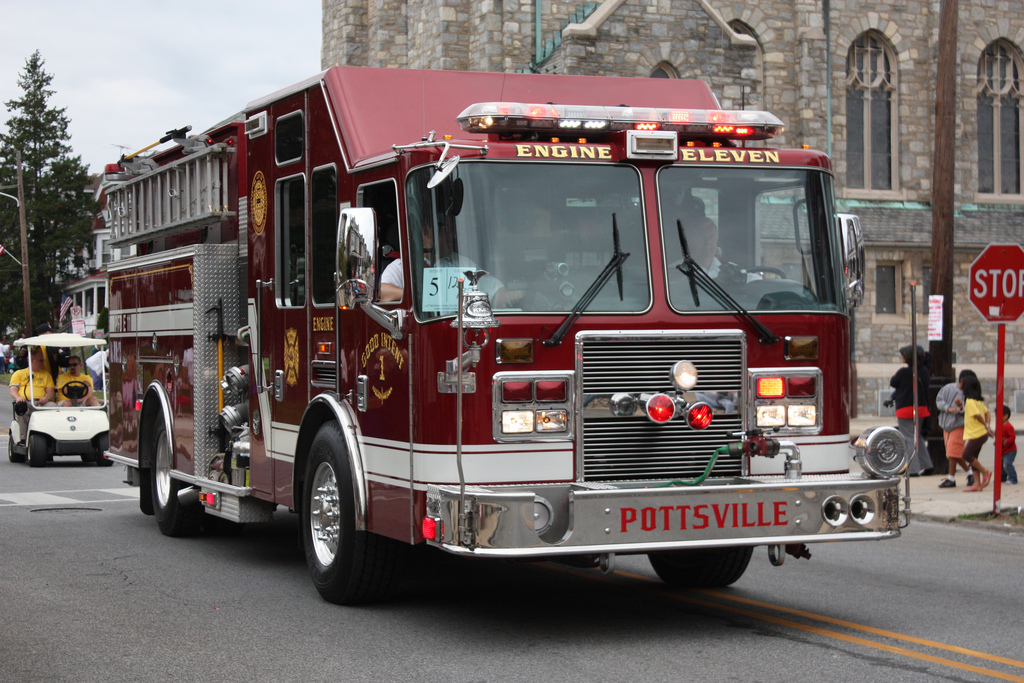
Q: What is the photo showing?
A: It is showing a street.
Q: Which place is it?
A: It is a street.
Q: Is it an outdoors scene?
A: Yes, it is outdoors.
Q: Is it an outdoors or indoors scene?
A: It is outdoors.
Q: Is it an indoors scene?
A: No, it is outdoors.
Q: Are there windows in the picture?
A: Yes, there is a window.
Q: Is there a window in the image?
A: Yes, there is a window.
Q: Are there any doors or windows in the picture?
A: Yes, there is a window.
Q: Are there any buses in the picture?
A: No, there are no buses.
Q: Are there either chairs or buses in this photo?
A: No, there are no buses or chairs.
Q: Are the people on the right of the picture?
A: Yes, the people are on the right of the image.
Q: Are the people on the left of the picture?
A: No, the people are on the right of the image.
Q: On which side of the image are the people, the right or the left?
A: The people are on the right of the image.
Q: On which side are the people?
A: The people are on the right of the image.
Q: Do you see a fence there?
A: No, there are no fences.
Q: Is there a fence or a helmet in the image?
A: No, there are no fences or helmets.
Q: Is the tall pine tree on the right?
A: No, the pine tree is on the left of the image.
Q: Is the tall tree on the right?
A: No, the pine tree is on the left of the image.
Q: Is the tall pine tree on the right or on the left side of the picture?
A: The pine is on the left of the image.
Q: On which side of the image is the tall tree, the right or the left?
A: The pine is on the left of the image.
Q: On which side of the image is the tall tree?
A: The pine is on the left of the image.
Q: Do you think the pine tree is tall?
A: Yes, the pine tree is tall.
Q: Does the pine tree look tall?
A: Yes, the pine tree is tall.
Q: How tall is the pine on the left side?
A: The pine tree is tall.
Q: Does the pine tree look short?
A: No, the pine tree is tall.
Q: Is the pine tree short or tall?
A: The pine tree is tall.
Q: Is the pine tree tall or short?
A: The pine tree is tall.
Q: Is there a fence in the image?
A: No, there are no fences.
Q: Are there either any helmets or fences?
A: No, there are no fences or helmets.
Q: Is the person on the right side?
A: Yes, the person is on the right of the image.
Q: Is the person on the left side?
A: No, the person is on the right of the image.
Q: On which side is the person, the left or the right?
A: The person is on the right of the image.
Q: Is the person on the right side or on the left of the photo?
A: The person is on the right of the image.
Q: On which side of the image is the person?
A: The person is on the right of the image.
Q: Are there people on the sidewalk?
A: Yes, there is a person on the sidewalk.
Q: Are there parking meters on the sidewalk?
A: No, there is a person on the sidewalk.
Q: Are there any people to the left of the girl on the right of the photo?
A: Yes, there is a person to the left of the girl.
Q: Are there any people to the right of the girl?
A: No, the person is to the left of the girl.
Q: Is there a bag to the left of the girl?
A: No, there is a person to the left of the girl.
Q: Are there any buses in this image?
A: No, there are no buses.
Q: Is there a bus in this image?
A: No, there are no buses.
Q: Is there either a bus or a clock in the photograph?
A: No, there are no buses or clocks.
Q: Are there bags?
A: No, there are no bags.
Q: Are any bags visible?
A: No, there are no bags.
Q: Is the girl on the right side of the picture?
A: Yes, the girl is on the right of the image.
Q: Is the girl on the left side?
A: No, the girl is on the right of the image.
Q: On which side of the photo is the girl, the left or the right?
A: The girl is on the right of the image.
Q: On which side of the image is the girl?
A: The girl is on the right of the image.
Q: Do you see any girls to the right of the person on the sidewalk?
A: Yes, there is a girl to the right of the person.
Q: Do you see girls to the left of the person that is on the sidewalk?
A: No, the girl is to the right of the person.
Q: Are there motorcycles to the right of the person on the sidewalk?
A: No, there is a girl to the right of the person.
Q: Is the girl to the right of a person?
A: Yes, the girl is to the right of a person.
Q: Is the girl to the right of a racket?
A: No, the girl is to the right of a person.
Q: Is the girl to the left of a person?
A: No, the girl is to the right of a person.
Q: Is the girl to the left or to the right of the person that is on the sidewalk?
A: The girl is to the right of the person.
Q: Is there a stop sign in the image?
A: Yes, there is a stop sign.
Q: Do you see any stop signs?
A: Yes, there is a stop sign.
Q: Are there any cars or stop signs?
A: Yes, there is a stop sign.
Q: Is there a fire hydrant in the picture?
A: No, there are no fire hydrants.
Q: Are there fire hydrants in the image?
A: No, there are no fire hydrants.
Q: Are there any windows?
A: Yes, there is a window.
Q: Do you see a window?
A: Yes, there is a window.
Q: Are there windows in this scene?
A: Yes, there is a window.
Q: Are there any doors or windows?
A: Yes, there is a window.